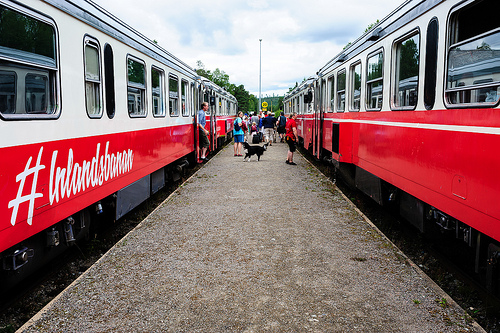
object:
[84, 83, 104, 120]
window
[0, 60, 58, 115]
window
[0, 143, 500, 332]
ground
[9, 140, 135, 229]
logo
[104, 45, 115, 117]
window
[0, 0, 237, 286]
train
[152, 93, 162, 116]
window